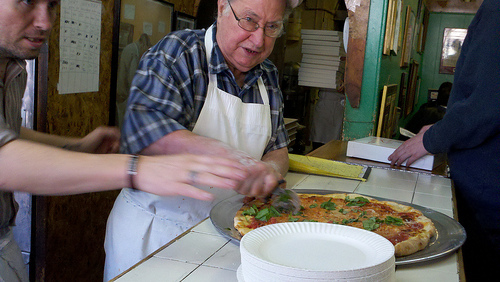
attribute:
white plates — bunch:
[231, 218, 396, 279]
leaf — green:
[364, 217, 379, 231]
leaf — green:
[383, 214, 402, 224]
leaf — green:
[320, 200, 335, 210]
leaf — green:
[254, 205, 274, 223]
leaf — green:
[241, 205, 258, 216]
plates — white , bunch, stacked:
[234, 220, 393, 280]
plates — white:
[230, 215, 406, 279]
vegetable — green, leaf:
[273, 190, 291, 220]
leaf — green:
[334, 210, 380, 233]